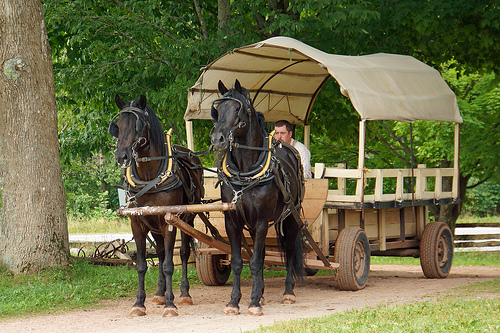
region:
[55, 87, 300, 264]
two horses in front of man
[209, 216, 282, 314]
front legs of the horses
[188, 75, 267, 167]
head of the horse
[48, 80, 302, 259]
two brown horses in front of carriage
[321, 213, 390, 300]
tire of the carriage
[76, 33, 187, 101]
leaves on the tree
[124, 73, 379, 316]
two horses on carriage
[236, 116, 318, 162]
man is behind horses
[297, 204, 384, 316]
black and brown wheels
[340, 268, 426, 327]
path is light brown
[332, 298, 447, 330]
green grass near carriage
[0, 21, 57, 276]
tall and brown tree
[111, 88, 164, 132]
black ears on horse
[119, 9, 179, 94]
green trees behind carriage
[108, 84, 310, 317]
two black horses pulling carriage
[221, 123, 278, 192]
yellow harness around black horse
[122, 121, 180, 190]
yellow harness around black horse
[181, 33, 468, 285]
carriage with cream colored canopy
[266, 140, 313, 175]
man wearing white shirt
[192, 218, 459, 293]
three dusty tires visible on carriage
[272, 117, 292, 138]
man sitting on carriage has short brown hair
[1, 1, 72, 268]
large brown tree trunk next to horses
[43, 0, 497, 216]
lush green trees in the background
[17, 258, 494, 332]
dirt path with horses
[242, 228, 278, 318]
leg of a horse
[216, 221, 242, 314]
leg of a horse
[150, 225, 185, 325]
leg of a horse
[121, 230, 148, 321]
leg of a horse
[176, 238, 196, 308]
leg of a horse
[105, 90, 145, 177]
face of a horse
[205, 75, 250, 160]
face of a horse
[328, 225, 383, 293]
wheel on a wagon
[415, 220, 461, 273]
wheel on a wagon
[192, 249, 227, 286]
wheel of a wagon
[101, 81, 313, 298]
Horses in the photo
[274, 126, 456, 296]
A cart in the photo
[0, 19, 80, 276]
A tree trunk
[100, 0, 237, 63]
Leaves in the photo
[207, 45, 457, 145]
Shade in the photo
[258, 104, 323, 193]
A man riding a horse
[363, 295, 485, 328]
Grass in the field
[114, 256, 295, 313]
Hooves of horses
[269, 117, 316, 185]
A man riding horse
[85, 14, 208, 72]
Trees growing in the background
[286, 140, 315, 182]
man wearing a white shirt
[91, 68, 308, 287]
horses pulling a wagon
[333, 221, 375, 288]
rubber tires on a carriage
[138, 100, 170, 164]
hair on a horse